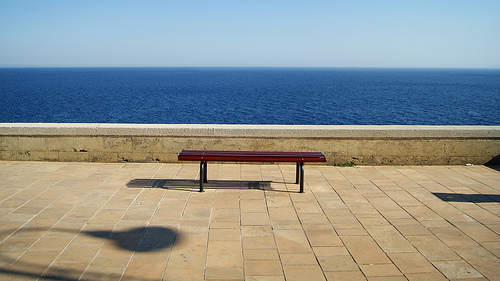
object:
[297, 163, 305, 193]
leg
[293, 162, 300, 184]
leg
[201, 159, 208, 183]
leg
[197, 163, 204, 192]
leg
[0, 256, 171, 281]
shadow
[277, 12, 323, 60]
clouds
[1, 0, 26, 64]
blue sky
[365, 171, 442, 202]
tiels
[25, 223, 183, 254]
shadow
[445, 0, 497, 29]
sky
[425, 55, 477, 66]
white clouds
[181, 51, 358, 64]
blue sky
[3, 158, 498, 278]
ground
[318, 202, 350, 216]
brick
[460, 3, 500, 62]
clouds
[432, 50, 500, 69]
sky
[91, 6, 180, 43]
sky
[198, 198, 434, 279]
floor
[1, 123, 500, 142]
concrete wall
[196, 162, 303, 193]
iron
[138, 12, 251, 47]
sky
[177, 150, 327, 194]
bench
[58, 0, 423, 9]
clouds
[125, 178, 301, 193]
shadow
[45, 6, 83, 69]
sky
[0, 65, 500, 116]
beach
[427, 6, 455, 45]
clouds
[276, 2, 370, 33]
sky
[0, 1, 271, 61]
clouds